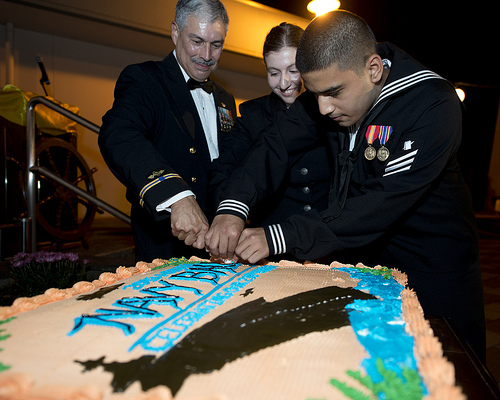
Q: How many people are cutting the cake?
A: 3.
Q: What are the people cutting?
A: A cake.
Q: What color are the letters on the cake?
A: Blue.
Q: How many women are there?
A: 1.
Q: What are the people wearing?
A: A uniform.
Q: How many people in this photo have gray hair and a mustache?
A: One.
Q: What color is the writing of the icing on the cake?
A: Blue.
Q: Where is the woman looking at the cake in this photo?
A: In the middle of two other people.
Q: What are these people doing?
A: Cutting a cake.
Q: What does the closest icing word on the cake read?
A: NAVY.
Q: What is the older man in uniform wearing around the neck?
A: A bowtie.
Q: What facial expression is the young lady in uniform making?
A: A smile.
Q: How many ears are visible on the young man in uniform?
A: One.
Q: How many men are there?
A: 2.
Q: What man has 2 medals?
A: Man on right.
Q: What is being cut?
A: Cake.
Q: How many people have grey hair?
A: 1.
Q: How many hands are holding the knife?
A: Three.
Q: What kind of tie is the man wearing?
A: Bow.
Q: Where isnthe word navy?
A: Top of cake.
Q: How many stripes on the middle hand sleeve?
A: 3.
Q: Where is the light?
A: Over head.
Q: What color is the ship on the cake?
A: Black.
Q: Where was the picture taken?
A: At a party.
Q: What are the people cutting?
A: A cake.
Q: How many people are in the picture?
A: Three.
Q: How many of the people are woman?
A: One.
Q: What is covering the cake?
A: Icing.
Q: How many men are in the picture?
A: Two.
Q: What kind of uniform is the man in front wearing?
A: Navy.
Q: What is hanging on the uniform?
A: Medals.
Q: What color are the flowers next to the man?
A: Purple.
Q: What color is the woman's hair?
A: Brown.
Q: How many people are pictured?
A: Three.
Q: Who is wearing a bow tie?
A: Man on left.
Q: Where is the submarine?
A: On the cake.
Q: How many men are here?
A: Two.